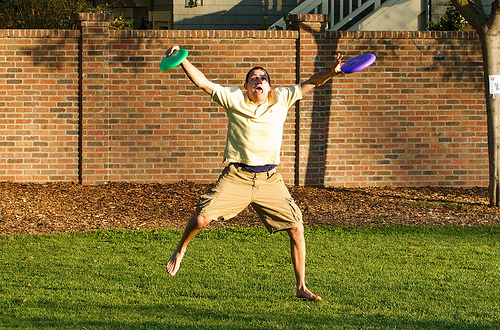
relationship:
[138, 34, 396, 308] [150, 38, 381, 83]
man holding discs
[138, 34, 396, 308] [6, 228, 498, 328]
man over grass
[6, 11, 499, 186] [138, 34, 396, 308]
wall behind man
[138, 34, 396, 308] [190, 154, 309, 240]
man in shorts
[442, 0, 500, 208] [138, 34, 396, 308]
tree behind man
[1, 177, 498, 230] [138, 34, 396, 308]
mulch behind man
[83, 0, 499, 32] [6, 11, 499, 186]
house behind wall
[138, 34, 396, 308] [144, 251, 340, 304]
man has feet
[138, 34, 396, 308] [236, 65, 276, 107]
man has head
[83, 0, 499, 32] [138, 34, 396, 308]
house behind man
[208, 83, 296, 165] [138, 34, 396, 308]
shirt on man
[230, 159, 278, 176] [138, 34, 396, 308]
boxers on man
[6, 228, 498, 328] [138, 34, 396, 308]
grass underneath man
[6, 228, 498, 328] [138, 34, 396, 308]
grass near man